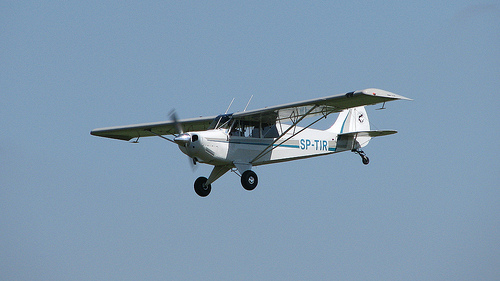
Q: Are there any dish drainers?
A: No, there are no dish drainers.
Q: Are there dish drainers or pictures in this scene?
A: No, there are no dish drainers or pictures.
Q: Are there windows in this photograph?
A: Yes, there are windows.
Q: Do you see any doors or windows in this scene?
A: Yes, there are windows.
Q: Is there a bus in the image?
A: No, there are no buses.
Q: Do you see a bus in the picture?
A: No, there are no buses.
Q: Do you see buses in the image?
A: No, there are no buses.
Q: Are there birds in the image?
A: No, there are no birds.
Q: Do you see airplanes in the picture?
A: Yes, there is an airplane.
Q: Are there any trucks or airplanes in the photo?
A: Yes, there is an airplane.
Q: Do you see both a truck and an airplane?
A: No, there is an airplane but no trucks.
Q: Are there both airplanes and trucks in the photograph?
A: No, there is an airplane but no trucks.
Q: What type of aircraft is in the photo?
A: The aircraft is an airplane.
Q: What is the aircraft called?
A: The aircraft is an airplane.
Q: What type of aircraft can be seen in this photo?
A: The aircraft is an airplane.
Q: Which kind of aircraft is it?
A: The aircraft is an airplane.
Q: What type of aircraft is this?
A: That is an airplane.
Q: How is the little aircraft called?
A: The aircraft is an airplane.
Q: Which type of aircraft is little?
A: The aircraft is an airplane.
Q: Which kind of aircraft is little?
A: The aircraft is an airplane.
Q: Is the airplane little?
A: Yes, the airplane is little.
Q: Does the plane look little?
A: Yes, the plane is little.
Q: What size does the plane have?
A: The plane has little size.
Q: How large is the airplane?
A: The airplane is little.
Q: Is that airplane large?
A: No, the airplane is little.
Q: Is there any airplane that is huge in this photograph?
A: No, there is an airplane but it is little.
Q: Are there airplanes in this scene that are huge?
A: No, there is an airplane but it is little.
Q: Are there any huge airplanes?
A: No, there is an airplane but it is little.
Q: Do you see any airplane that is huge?
A: No, there is an airplane but it is little.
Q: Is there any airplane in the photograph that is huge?
A: No, there is an airplane but it is little.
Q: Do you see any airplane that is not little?
A: No, there is an airplane but it is little.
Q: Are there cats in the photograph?
A: No, there are no cats.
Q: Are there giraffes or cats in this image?
A: No, there are no cats or giraffes.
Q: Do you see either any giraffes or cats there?
A: No, there are no cats or giraffes.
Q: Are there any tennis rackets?
A: No, there are no tennis rackets.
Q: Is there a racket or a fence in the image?
A: No, there are no rackets or fences.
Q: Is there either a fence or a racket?
A: No, there are no rackets or fences.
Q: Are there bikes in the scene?
A: No, there are no bikes.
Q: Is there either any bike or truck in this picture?
A: No, there are no bikes or trucks.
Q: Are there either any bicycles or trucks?
A: No, there are no bicycles or trucks.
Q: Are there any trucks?
A: No, there are no trucks.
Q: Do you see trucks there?
A: No, there are no trucks.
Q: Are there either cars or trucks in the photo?
A: No, there are no trucks or cars.